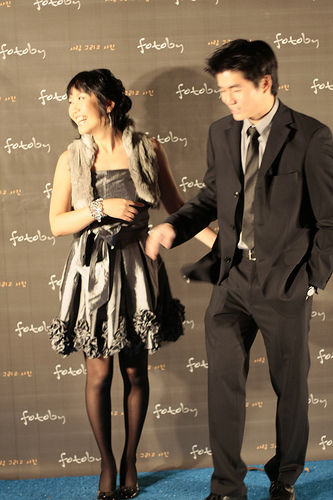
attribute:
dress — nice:
[42, 234, 185, 361]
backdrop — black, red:
[104, 1, 153, 61]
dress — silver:
[67, 177, 183, 356]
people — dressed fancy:
[42, 37, 319, 471]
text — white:
[17, 409, 66, 424]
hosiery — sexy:
[85, 354, 150, 496]